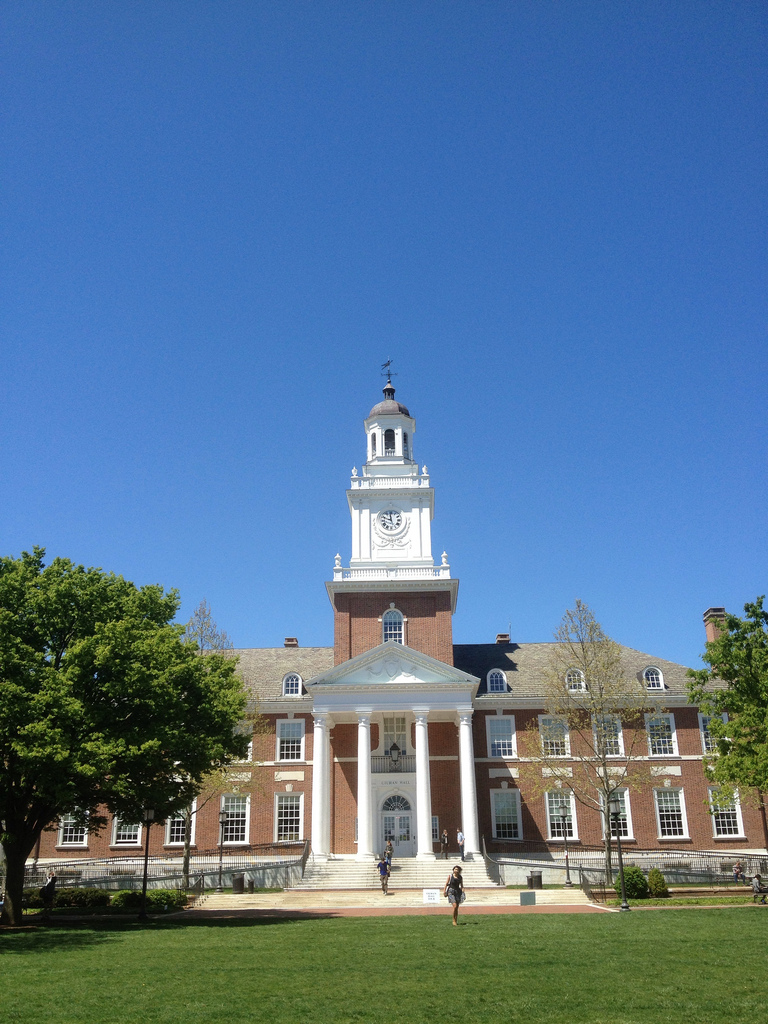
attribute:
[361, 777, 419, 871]
door — white 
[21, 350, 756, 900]
building — beautiful 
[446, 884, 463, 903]
skirt — gray 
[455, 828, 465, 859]
person — standing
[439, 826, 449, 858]
person — standing